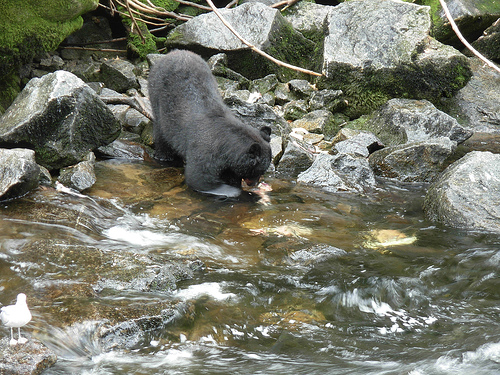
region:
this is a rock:
[3, 69, 118, 176]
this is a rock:
[292, 131, 347, 207]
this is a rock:
[415, 142, 497, 259]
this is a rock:
[359, 83, 464, 180]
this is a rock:
[249, 103, 294, 157]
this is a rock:
[287, 84, 334, 134]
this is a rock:
[327, 2, 437, 116]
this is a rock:
[78, 41, 142, 113]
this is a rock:
[172, 5, 299, 120]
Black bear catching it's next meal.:
[141, 45, 272, 208]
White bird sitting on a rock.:
[0, 287, 41, 351]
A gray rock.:
[318, 0, 470, 98]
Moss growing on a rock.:
[0, 1, 90, 55]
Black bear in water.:
[143, 51, 276, 209]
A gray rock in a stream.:
[300, 141, 380, 238]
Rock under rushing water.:
[358, 220, 415, 255]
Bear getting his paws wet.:
[146, 51, 274, 206]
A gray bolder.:
[313, 1, 473, 98]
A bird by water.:
[0, 288, 37, 348]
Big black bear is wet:
[145, 48, 275, 199]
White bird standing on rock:
[0, 291, 34, 348]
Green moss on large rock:
[260, 20, 314, 77]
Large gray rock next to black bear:
[0, 72, 123, 163]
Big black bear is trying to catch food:
[142, 48, 274, 200]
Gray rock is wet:
[0, 143, 43, 202]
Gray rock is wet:
[0, 69, 125, 162]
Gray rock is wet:
[424, 148, 499, 241]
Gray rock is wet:
[297, 150, 379, 200]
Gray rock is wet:
[59, 148, 97, 190]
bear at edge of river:
[145, 50, 283, 200]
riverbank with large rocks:
[2, 3, 494, 373]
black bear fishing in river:
[144, 50, 274, 195]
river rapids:
[2, 182, 499, 374]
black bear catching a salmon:
[148, 49, 275, 205]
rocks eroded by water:
[298, 99, 499, 241]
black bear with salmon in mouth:
[148, 49, 271, 204]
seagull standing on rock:
[1, 292, 32, 345]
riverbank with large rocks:
[0, 1, 446, 170]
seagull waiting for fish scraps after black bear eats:
[0, 1, 495, 373]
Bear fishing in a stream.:
[147, 48, 272, 196]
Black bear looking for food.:
[147, 48, 272, 198]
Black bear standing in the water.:
[149, 49, 271, 196]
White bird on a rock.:
[0, 293, 31, 343]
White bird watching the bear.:
[0, 293, 31, 343]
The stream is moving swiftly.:
[1, 158, 498, 373]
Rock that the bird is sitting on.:
[0, 330, 57, 374]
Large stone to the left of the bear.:
[1, 71, 121, 171]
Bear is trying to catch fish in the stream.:
[149, 49, 271, 201]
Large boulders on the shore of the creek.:
[0, 1, 499, 235]